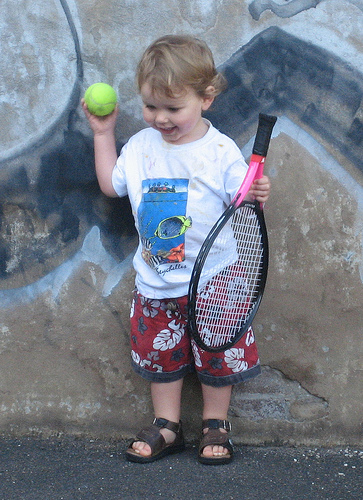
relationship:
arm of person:
[92, 114, 127, 199] [69, 38, 310, 376]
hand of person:
[79, 94, 119, 132] [93, 36, 273, 354]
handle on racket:
[251, 112, 277, 157] [185, 111, 276, 352]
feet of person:
[128, 416, 232, 460] [132, 46, 274, 211]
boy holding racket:
[79, 32, 270, 465] [161, 98, 295, 391]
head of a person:
[119, 35, 240, 140] [73, 28, 320, 471]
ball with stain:
[85, 83, 117, 116] [95, 103, 106, 114]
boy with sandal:
[79, 32, 270, 465] [197, 419, 233, 464]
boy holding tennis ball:
[79, 32, 270, 465] [78, 79, 118, 118]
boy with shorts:
[79, 32, 270, 465] [126, 256, 263, 388]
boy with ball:
[79, 32, 270, 465] [84, 81, 117, 115]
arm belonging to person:
[83, 114, 127, 199] [78, 31, 270, 465]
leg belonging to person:
[119, 294, 185, 466] [78, 31, 270, 465]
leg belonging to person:
[184, 302, 253, 461] [78, 31, 270, 465]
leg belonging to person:
[189, 302, 239, 431] [78, 31, 270, 465]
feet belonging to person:
[130, 416, 182, 455] [78, 31, 270, 465]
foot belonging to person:
[200, 423, 229, 456] [78, 31, 270, 465]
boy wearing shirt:
[73, 32, 272, 465] [111, 116, 250, 298]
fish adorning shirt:
[149, 216, 191, 240] [111, 116, 250, 298]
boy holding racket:
[73, 32, 272, 465] [187, 114, 269, 354]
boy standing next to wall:
[73, 32, 272, 465] [1, 1, 350, 449]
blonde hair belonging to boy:
[134, 34, 226, 95] [73, 32, 272, 465]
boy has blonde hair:
[73, 32, 272, 465] [131, 38, 226, 95]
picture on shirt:
[127, 172, 194, 274] [111, 116, 250, 298]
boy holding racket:
[73, 32, 272, 465] [184, 105, 285, 359]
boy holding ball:
[73, 32, 272, 465] [79, 78, 117, 115]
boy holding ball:
[73, 32, 272, 465] [86, 83, 118, 117]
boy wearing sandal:
[73, 32, 272, 465] [123, 417, 183, 463]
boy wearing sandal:
[73, 32, 272, 465] [197, 419, 233, 464]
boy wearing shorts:
[73, 32, 272, 465] [124, 274, 265, 388]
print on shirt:
[130, 168, 191, 285] [111, 116, 250, 298]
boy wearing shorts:
[73, 32, 272, 465] [126, 256, 263, 388]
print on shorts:
[128, 262, 261, 382] [126, 256, 263, 388]